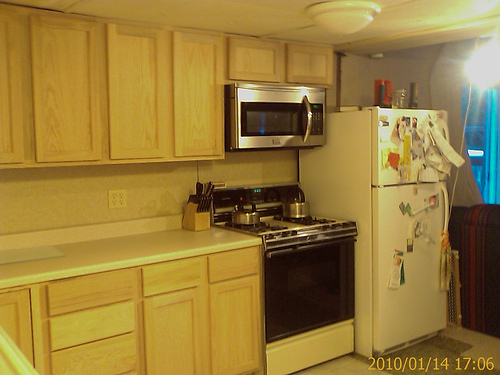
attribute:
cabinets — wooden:
[0, 2, 335, 374]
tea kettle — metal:
[232, 198, 260, 225]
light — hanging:
[446, 31, 500, 106]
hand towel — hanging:
[440, 230, 454, 291]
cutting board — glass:
[1, 246, 65, 267]